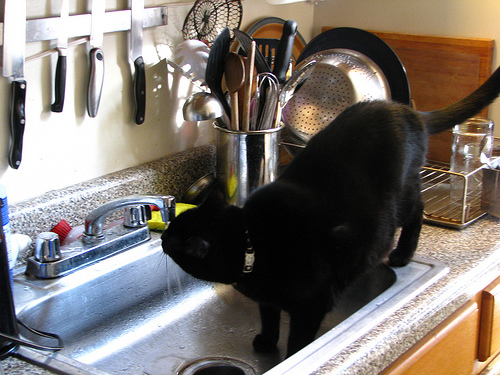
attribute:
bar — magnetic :
[0, 1, 170, 51]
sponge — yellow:
[149, 200, 194, 230]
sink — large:
[6, 194, 448, 373]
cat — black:
[144, 61, 498, 361]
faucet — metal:
[77, 188, 180, 242]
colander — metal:
[282, 43, 396, 150]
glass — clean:
[435, 114, 495, 230]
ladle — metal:
[179, 86, 233, 135]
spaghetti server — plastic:
[197, 21, 242, 99]